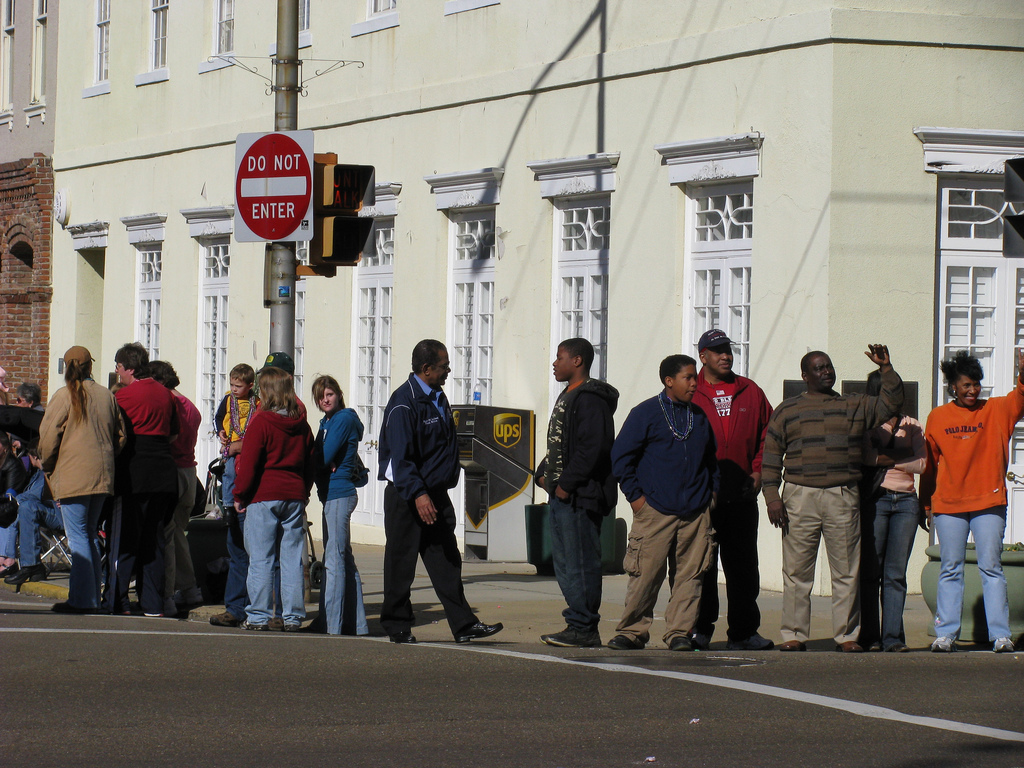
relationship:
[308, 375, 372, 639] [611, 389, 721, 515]
girl in blue blue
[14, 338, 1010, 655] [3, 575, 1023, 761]
people on street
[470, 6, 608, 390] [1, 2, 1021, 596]
shadow on wall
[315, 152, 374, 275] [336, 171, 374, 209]
light for directions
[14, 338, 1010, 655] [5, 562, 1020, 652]
people on curb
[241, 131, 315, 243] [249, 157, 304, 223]
sign with warning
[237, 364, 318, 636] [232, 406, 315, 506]
woman wearing hoodie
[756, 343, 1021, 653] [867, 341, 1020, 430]
two people waving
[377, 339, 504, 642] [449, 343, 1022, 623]
man looking right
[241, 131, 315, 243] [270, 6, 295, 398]
sign on pole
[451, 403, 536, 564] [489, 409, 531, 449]
box for ups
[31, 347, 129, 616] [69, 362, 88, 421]
woman has ponytail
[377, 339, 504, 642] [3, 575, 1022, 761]
man in street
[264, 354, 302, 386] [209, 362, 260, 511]
man holding child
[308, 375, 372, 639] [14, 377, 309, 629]
woman looking left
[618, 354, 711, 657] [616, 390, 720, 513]
man wearing blue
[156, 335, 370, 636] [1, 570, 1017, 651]
people on curb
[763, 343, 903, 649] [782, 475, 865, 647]
man wearing pants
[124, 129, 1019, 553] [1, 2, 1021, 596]
windows on wall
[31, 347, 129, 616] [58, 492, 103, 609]
woman wearing jeans